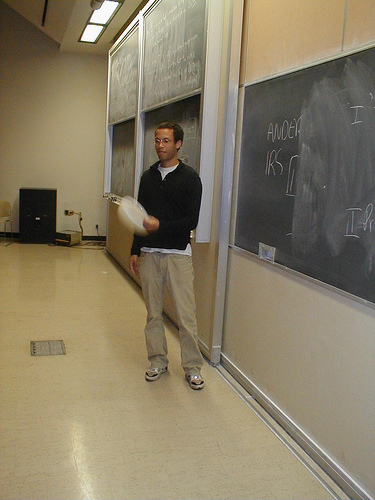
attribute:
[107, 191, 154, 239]
frisbee — white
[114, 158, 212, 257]
sweater — long sleeve, black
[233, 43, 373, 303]
blackboard — wiped, black, green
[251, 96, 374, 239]
chalk writing — white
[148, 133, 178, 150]
glasses — wire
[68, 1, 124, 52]
lights — on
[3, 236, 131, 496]
floor — waxed, tan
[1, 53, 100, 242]
wall — beige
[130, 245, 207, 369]
pants — brown, beige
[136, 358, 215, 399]
shoes — white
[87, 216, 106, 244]
speaker — black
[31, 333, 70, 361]
vent — white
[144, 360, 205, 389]
shoes — tennis shoes